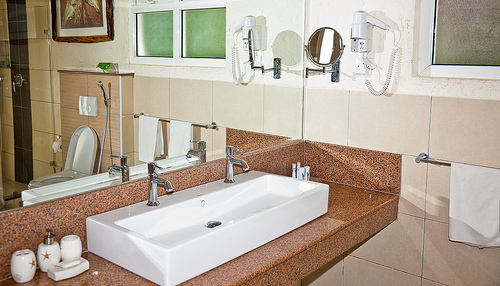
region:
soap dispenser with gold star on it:
[31, 224, 68, 275]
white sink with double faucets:
[78, 144, 352, 284]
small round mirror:
[302, 21, 348, 86]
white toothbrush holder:
[6, 245, 39, 284]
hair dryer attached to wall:
[348, 5, 410, 102]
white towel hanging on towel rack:
[407, 148, 498, 252]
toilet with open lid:
[19, 122, 107, 201]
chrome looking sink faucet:
[143, 158, 177, 208]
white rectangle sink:
[65, 164, 349, 284]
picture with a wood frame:
[47, 0, 116, 49]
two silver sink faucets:
[138, 150, 262, 202]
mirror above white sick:
[1, 3, 313, 201]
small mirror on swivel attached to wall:
[298, 25, 345, 78]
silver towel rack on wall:
[418, 148, 499, 185]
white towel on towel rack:
[447, 165, 496, 251]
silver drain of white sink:
[204, 215, 219, 227]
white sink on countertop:
[83, 165, 339, 285]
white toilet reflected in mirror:
[21, 134, 106, 186]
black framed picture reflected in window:
[50, 5, 118, 50]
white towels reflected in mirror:
[127, 105, 193, 160]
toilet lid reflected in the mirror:
[62, 123, 97, 178]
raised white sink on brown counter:
[82, 145, 332, 282]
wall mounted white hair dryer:
[341, 8, 408, 105]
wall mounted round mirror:
[305, 22, 348, 86]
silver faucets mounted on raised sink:
[102, 138, 254, 211]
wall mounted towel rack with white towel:
[412, 145, 493, 247]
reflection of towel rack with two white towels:
[127, 105, 218, 165]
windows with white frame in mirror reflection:
[122, 0, 234, 68]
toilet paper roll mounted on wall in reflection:
[48, 130, 68, 157]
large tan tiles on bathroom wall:
[301, 86, 435, 159]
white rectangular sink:
[96, 140, 292, 270]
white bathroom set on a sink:
[6, 223, 96, 280]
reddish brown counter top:
[19, 148, 407, 277]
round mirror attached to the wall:
[300, 18, 345, 83]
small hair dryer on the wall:
[347, 8, 402, 102]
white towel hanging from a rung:
[421, 148, 496, 250]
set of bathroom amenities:
[287, 159, 311, 180]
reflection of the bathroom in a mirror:
[4, 5, 307, 147]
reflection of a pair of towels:
[129, 112, 196, 167]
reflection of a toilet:
[26, 123, 103, 200]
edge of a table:
[254, 218, 261, 230]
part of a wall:
[426, 220, 463, 248]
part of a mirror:
[78, 129, 105, 164]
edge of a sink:
[357, 186, 368, 211]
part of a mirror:
[290, 43, 295, 65]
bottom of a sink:
[373, 223, 378, 233]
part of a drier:
[357, 58, 376, 75]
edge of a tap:
[166, 188, 174, 196]